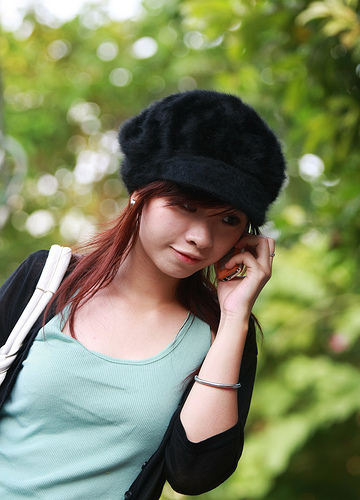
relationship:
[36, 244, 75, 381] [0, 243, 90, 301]
strap over shoulder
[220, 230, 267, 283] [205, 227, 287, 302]
cellphone in hand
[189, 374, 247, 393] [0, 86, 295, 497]
bracelet on girl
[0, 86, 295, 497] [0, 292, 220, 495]
girl wearing shirt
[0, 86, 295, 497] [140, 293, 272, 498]
girl wearing sweater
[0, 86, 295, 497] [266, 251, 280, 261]
girl wearing ring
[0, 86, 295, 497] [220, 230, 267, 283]
girl on cellphone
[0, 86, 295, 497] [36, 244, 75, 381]
girl carrying strap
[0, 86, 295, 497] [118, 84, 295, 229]
girl wearing hat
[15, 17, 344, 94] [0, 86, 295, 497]
trees are behind girl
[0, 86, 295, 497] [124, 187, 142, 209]
girl wearing earring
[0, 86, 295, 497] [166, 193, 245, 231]
girl has eyes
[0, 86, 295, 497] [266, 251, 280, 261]
girl wears ring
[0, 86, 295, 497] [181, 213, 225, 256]
girl has nose